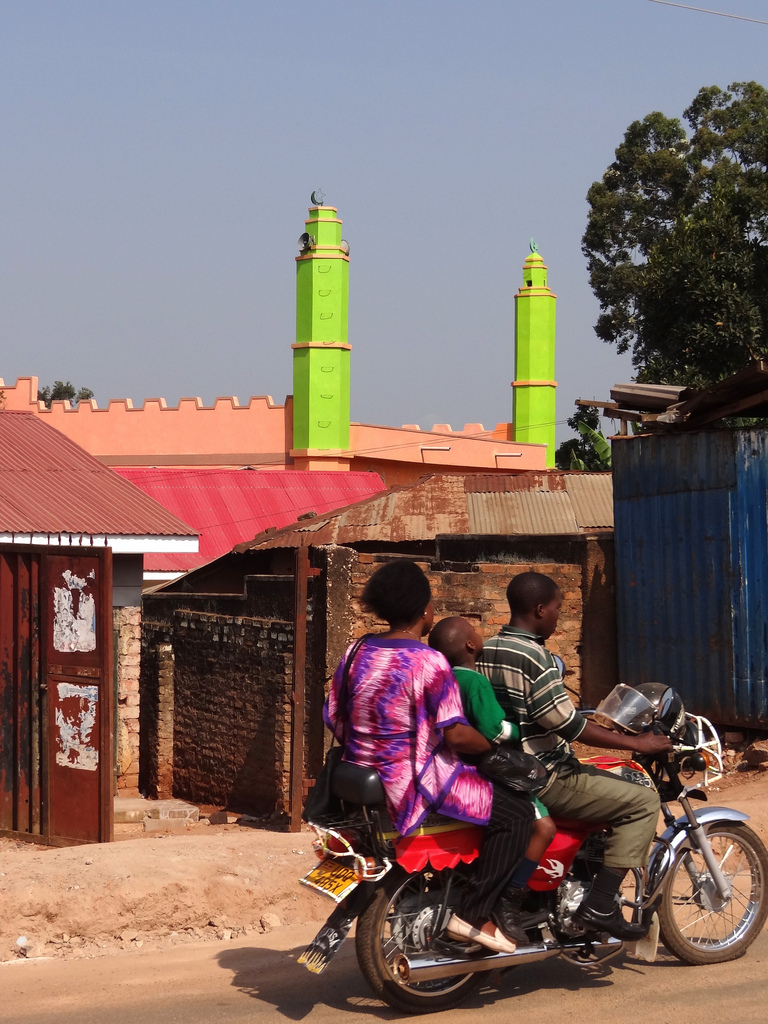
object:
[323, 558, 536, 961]
woman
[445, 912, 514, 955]
loafer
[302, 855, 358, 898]
yellow plate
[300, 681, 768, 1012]
bike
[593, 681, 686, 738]
helmet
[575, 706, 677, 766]
handlebars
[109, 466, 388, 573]
red roof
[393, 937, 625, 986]
exhaust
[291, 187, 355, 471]
tower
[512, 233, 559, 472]
tower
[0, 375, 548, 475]
building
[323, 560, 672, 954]
people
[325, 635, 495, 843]
dress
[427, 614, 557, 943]
boy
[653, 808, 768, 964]
front tire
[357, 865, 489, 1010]
back tire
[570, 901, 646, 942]
shoe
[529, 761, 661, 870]
pants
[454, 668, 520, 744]
shirt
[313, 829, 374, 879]
light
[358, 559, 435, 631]
hair